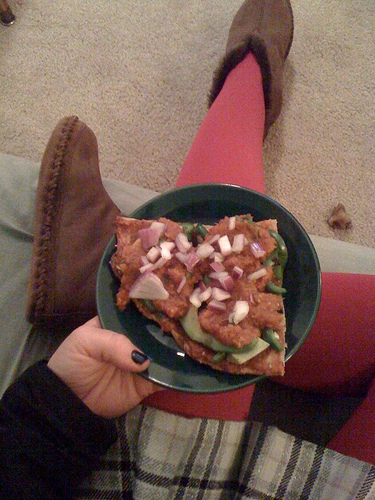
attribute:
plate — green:
[65, 171, 350, 402]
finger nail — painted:
[114, 342, 195, 409]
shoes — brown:
[26, 3, 302, 332]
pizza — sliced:
[97, 192, 292, 363]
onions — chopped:
[133, 228, 241, 272]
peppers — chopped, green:
[176, 227, 278, 362]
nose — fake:
[308, 189, 359, 242]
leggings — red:
[162, 44, 372, 474]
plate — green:
[69, 166, 326, 399]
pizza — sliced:
[100, 208, 295, 393]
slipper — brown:
[20, 112, 133, 343]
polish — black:
[119, 343, 155, 368]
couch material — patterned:
[65, 387, 370, 498]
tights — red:
[136, 80, 370, 412]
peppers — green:
[264, 226, 293, 302]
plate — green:
[90, 172, 331, 400]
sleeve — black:
[0, 340, 138, 495]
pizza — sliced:
[105, 210, 292, 383]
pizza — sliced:
[108, 219, 303, 384]